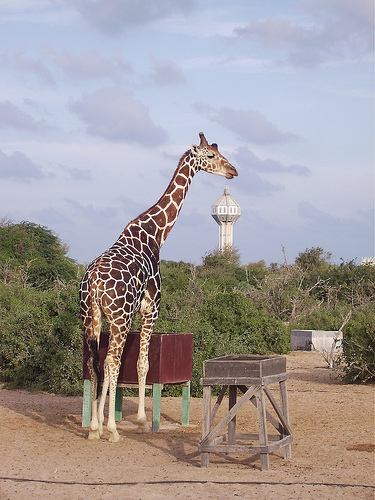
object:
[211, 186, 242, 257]
tower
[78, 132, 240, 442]
giraffe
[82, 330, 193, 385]
box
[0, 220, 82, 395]
tree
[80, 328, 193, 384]
water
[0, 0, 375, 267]
sky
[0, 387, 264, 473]
shadow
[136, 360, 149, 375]
knee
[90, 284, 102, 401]
tail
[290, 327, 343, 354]
structure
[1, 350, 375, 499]
sand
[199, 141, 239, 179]
head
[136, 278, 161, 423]
leg